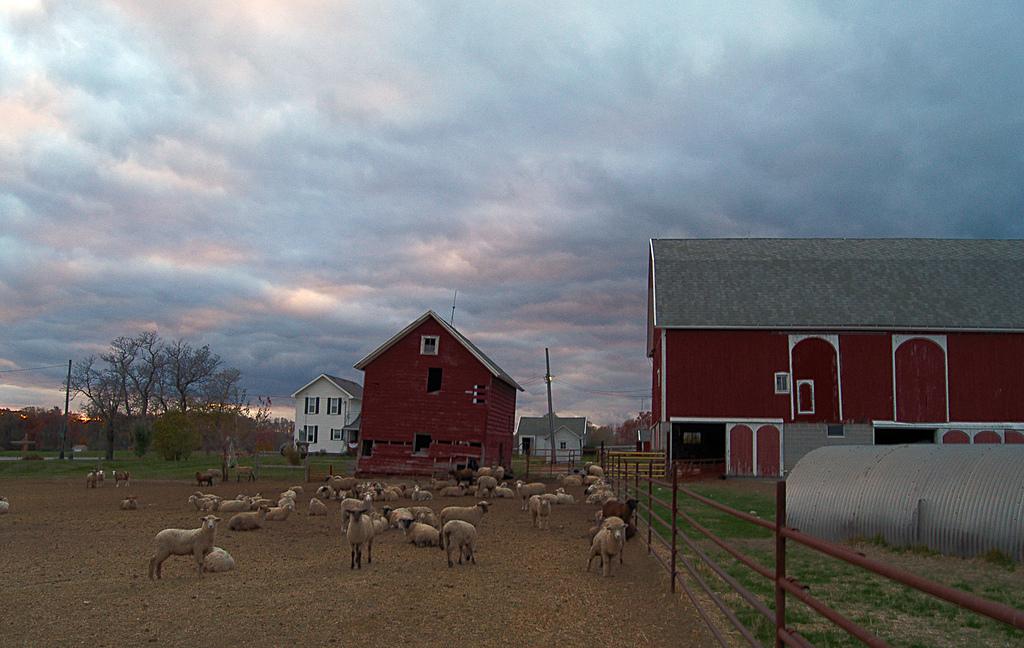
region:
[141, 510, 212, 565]
white sheep standing in dirt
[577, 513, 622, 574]
white sheep that is standing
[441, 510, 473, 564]
white sheep that is standing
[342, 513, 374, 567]
white sheep that is standing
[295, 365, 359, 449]
large white farm house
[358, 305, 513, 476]
large red barn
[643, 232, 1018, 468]
large red barn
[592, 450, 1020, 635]
red metal fencerails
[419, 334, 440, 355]
small white window in a red building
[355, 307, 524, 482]
the barn is tall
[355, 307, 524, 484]
the barn is tall and red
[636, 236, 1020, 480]
the barn is very large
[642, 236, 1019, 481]
the barn is red and white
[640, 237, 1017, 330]
the roof is long and gray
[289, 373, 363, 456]
the house is large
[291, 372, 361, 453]
the house is white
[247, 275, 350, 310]
this portion of the sky is slightly shining in reddish white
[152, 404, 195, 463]
tree with green leaves in its branches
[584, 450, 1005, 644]
long fence made of poles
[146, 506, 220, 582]
the sheep is looking towards its right side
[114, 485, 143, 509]
the sheep is taking rest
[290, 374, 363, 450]
the building is painted in white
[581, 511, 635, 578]
a small brown sheep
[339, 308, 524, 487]
a red broken building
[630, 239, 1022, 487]
a large red barn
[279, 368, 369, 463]
a white house in the background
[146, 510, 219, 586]
a small brown sheep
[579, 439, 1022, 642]
a long red fence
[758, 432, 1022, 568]
a long metal pipe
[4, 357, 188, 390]
long eletrical wires connected to a pole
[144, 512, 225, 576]
A sheep in a field of grass.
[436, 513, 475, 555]
A sheep in a field of grass.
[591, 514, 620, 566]
A sheep in a field of grass.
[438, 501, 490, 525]
A sheep in a field of grass.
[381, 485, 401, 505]
A sheep in a field of grass.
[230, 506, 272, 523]
A sheep in a field of grass.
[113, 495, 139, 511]
A sheep in a field of grass.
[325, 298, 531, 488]
red wooden barn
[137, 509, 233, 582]
sheep with white wool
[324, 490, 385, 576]
sheep with white wool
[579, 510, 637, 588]
sheep with white wool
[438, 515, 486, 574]
sheep with white wool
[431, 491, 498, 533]
sheep with white wool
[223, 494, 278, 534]
sheep with white wool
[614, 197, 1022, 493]
Red wooden barn with grey roof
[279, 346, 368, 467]
white house with grey roof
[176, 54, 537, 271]
sky above the land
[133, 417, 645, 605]
animals on the ground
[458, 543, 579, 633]
dirt under the animals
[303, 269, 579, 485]
red structure on the ground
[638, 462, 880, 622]
poles next to the animals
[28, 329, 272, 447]
trees in the distance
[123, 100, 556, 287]
many clouds above land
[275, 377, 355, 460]
white house with windows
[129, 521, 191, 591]
back part of sheep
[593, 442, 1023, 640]
a rusty red fence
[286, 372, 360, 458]
an old white farmhouse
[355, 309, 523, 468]
an old red barn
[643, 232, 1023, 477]
a red and white barn